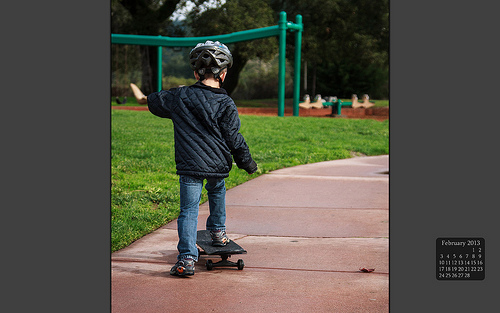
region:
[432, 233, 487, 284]
calendar from February 2013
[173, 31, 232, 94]
child wearing a helmet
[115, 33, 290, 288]
child on a skateboard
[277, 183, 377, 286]
part of a sidewalk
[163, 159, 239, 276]
a boy wearing jeans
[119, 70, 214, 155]
part of a black coat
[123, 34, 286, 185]
a boy wearing a black coat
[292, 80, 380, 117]
part of a playground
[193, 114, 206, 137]
child wearing dark jacket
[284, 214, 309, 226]
wet tan side walk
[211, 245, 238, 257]
back end of skateboard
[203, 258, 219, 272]
left wheel on board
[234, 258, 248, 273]
right wheel on board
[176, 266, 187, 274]
orange patch on sneaker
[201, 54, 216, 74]
back of childs helmet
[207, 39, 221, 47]
top of childs helmet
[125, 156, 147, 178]
green grass in field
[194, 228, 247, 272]
skateboard on the sidewalk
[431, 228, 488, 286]
calendar at the edge of the picture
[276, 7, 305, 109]
green poles of the playground equipment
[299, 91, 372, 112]
seesaw on the playground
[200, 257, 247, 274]
wheels on the skateboard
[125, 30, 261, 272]
child riding a skateboard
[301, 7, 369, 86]
trees behind the playground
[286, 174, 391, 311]
The ground is made of concrete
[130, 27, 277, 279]
The child is on his skate board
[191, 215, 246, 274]
The skateboard is the color black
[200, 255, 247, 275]
The wheels of the skate board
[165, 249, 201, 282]
The shoe of the child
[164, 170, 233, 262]
The child is wearing jeans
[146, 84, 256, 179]
The child has on a black jacket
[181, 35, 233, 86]
The boy has on a helmet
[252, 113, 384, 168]
The grass is short and green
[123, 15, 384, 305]
The playground is in the park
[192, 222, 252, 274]
a long black skateboard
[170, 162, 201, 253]
the leg of a boy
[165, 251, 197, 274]
a boy's gray tennis shoe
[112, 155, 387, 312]
part of a sidewalk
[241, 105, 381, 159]
a section of green grass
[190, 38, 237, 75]
a boy's helmet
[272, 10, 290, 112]
a tall green pole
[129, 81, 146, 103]
the hand of a boy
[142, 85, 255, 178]
a boy's black jacket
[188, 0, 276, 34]
green tree leaves